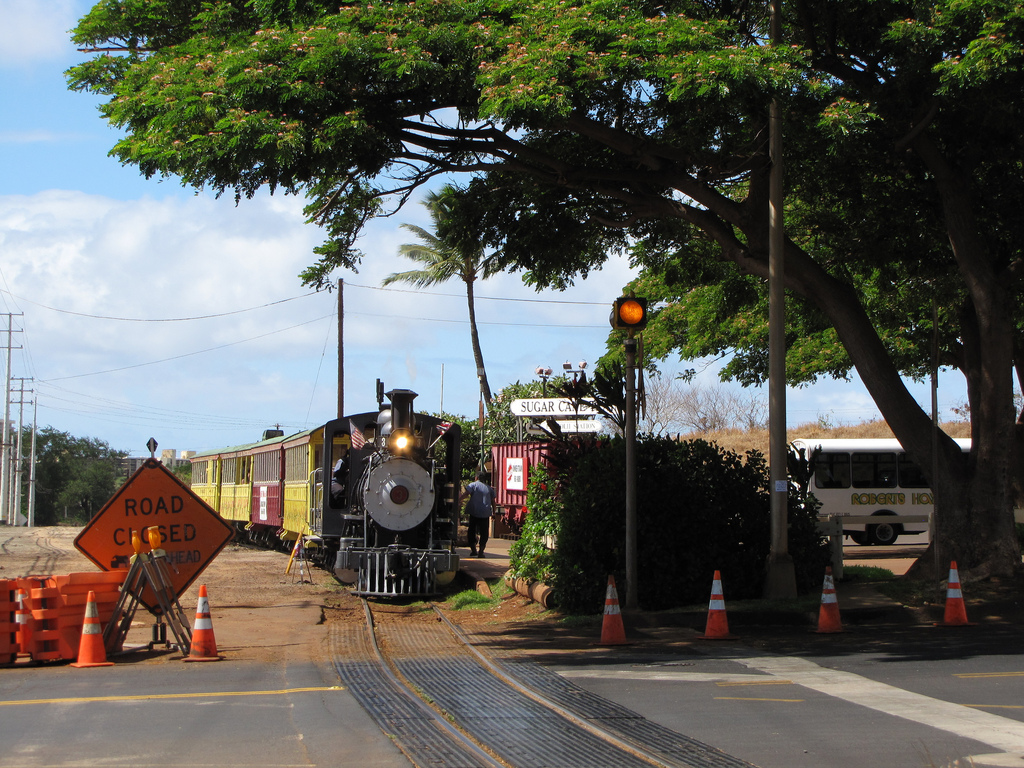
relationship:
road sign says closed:
[76, 461, 234, 616] [112, 520, 200, 549]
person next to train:
[463, 472, 500, 559] [154, 390, 465, 604]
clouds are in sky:
[0, 193, 644, 451] [1, 1, 648, 462]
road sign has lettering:
[76, 461, 234, 616] [111, 496, 201, 566]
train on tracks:
[154, 390, 465, 604] [360, 597, 664, 766]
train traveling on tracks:
[154, 390, 465, 604] [360, 597, 664, 766]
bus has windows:
[787, 435, 939, 546] [807, 447, 932, 486]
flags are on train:
[348, 415, 458, 456] [154, 390, 465, 604]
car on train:
[251, 443, 284, 533] [154, 390, 465, 604]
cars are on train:
[190, 428, 318, 544] [154, 390, 465, 604]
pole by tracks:
[757, 0, 803, 608] [360, 597, 664, 766]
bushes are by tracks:
[509, 427, 833, 614] [360, 597, 664, 766]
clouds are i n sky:
[0, 193, 644, 451] [1, 1, 648, 462]